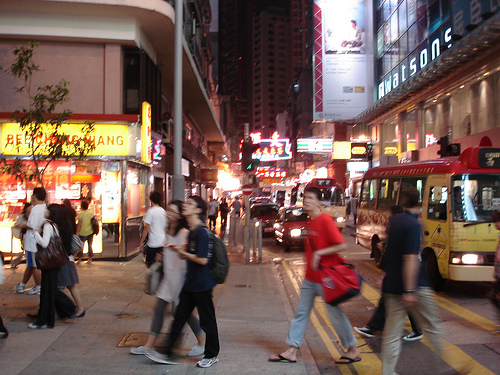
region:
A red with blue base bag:
[312, 245, 363, 313]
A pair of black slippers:
[262, 350, 364, 373]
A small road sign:
[233, 177, 264, 197]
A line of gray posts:
[217, 208, 268, 264]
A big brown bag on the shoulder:
[27, 215, 77, 275]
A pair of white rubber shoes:
[3, 275, 48, 297]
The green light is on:
[233, 137, 270, 175]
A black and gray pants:
[140, 284, 239, 362]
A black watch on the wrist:
[395, 285, 429, 311]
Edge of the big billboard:
[308, 97, 328, 131]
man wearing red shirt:
[316, 225, 332, 245]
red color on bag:
[335, 275, 350, 287]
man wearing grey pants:
[301, 295, 308, 309]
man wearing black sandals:
[265, 344, 299, 371]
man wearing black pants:
[207, 301, 213, 321]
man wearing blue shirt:
[194, 272, 202, 279]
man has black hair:
[201, 200, 206, 211]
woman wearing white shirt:
[169, 267, 175, 279]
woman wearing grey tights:
[156, 302, 163, 319]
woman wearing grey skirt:
[66, 267, 72, 279]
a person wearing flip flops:
[264, 336, 369, 373]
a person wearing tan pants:
[363, 278, 464, 373]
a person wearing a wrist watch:
[398, 282, 420, 299]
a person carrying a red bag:
[302, 250, 371, 311]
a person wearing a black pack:
[203, 226, 240, 291]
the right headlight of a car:
[282, 224, 306, 242]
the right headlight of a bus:
[461, 244, 486, 270]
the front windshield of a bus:
[450, 171, 498, 222]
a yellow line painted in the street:
[461, 301, 496, 341]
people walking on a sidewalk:
[216, 194, 252, 235]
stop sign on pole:
[239, 178, 254, 204]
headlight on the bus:
[450, 253, 480, 264]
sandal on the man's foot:
[266, 350, 302, 363]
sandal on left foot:
[332, 340, 363, 369]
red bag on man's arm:
[315, 260, 363, 305]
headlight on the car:
[289, 226, 299, 243]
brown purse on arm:
[36, 233, 61, 268]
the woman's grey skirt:
[61, 262, 81, 283]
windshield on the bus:
[451, 174, 498, 219]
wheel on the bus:
[421, 249, 443, 284]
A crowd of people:
[4, 173, 464, 373]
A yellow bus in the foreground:
[348, 135, 498, 310]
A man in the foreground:
[368, 174, 466, 371]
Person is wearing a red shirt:
[284, 215, 358, 294]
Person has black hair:
[291, 179, 329, 226]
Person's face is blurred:
[292, 181, 332, 225]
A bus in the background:
[276, 169, 355, 239]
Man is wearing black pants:
[137, 188, 237, 374]